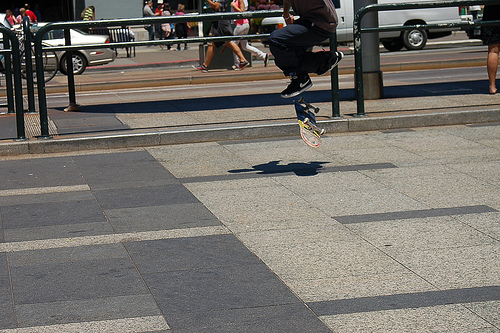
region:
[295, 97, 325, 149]
The skateboard the skater is using.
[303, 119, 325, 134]
The front wheels of the skateboard.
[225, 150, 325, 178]
The shadow of the skateboarder on the ground.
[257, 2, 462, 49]
The white truck driving in the street.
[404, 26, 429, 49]
The back tire of the pickup truck.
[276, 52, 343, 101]
The sneakers the skateboarder is wearing.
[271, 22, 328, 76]
The pants the skateboarder is wearing.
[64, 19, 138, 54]
The wrought iron bench across the street.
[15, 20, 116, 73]
The gold car in the street.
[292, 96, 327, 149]
skateboard that is upside down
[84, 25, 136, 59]
metal park bench on sidewalk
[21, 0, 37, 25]
person wearing a red tshirt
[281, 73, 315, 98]
black and white high top tennis shoe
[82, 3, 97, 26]
person wearing a striped shirt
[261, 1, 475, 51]
plain white pickup truck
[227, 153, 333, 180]
shadow of skateboarder on ground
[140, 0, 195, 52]
group of people walking together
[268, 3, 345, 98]
person doing skateboard tricks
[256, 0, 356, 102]
a person doing a skateboard trick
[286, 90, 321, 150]
A skateboard in the air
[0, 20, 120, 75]
A car on the road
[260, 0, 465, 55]
a white truck on the road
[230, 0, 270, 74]
a woman in a pink shirt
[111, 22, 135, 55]
a person sitting on a bench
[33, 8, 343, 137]
a metal guard rail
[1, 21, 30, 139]
a metal guard rail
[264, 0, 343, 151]
man flipping his skateboard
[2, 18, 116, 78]
tire on silver sedan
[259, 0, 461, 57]
tire on white pickup truck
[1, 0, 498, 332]
black railing next to ground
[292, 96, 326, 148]
wheel on skateboard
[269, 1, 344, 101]
man is wearing black tennis shoes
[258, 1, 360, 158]
the skater is jumping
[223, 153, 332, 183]
the shadow cast on the road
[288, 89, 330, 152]
the skater is upside down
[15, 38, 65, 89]
the wheel of a bike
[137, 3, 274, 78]
people in the street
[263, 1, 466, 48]
a truck on the street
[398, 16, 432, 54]
back wheel of a truck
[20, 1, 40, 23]
person wearing red top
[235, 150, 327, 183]
shadow underneath the skater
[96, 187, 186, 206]
darker tile of concrete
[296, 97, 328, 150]
the skateboard airborne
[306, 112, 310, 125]
wheel on the skateboard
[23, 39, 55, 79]
large round bike tire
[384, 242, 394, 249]
black spot on the ground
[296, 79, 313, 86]
nike emblem on the show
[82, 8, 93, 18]
yellow and black striped shirt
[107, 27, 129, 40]
metal bench people are sitting on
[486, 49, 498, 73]
the womans calve on the right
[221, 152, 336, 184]
Shadow across the ground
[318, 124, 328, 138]
Wheel of a skateboard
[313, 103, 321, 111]
Wheel of a skateboard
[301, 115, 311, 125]
Wheel of a skateboard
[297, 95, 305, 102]
Wheel of a skateboard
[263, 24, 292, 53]
Knee of a man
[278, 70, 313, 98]
Shoe on a man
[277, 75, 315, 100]
Black and white shoe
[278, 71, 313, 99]
Black and white shoe on a man